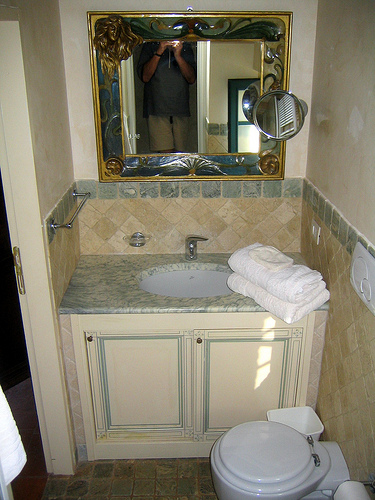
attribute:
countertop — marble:
[57, 251, 331, 314]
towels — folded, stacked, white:
[227, 242, 330, 323]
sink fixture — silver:
[184, 235, 208, 259]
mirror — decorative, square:
[86, 12, 293, 182]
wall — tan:
[300, 175, 373, 483]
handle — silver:
[47, 188, 89, 243]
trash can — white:
[267, 404, 324, 442]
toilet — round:
[209, 420, 350, 498]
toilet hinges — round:
[306, 435, 318, 464]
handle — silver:
[41, 188, 90, 233]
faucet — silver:
[184, 235, 207, 260]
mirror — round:
[254, 90, 308, 140]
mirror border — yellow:
[84, 8, 291, 181]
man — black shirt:
[142, 36, 198, 143]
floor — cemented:
[95, 474, 167, 496]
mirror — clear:
[79, 13, 298, 198]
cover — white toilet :
[204, 415, 328, 496]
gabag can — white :
[264, 391, 326, 440]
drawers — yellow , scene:
[82, 332, 229, 439]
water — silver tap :
[176, 224, 209, 264]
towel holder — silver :
[45, 181, 92, 243]